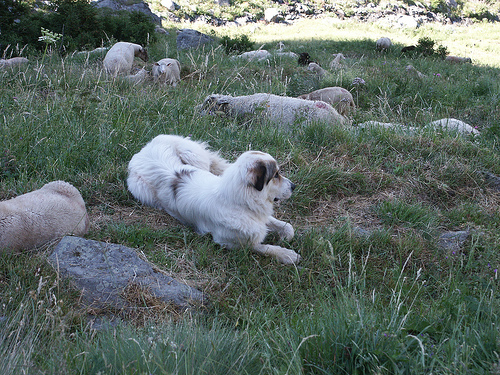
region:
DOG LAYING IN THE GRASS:
[125, 123, 317, 262]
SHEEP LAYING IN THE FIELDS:
[100, 41, 495, 156]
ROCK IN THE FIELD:
[42, 234, 214, 326]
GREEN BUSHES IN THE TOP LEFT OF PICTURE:
[2, 2, 183, 68]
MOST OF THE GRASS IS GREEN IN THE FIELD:
[3, 4, 488, 372]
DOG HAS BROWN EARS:
[235, 152, 297, 194]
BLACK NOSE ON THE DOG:
[282, 170, 299, 202]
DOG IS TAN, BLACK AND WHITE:
[123, 125, 322, 267]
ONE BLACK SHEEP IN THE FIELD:
[291, 46, 323, 76]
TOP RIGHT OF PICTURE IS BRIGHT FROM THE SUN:
[112, 0, 497, 78]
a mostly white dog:
[116, 112, 331, 315]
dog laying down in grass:
[107, 110, 322, 276]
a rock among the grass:
[44, 229, 224, 364]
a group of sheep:
[95, 20, 365, 134]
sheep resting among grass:
[90, 28, 368, 135]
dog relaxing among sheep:
[80, 33, 407, 258]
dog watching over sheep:
[67, 32, 434, 274]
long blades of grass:
[250, 258, 498, 355]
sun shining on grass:
[266, 8, 438, 70]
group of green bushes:
[4, 0, 139, 55]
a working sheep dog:
[104, 105, 336, 294]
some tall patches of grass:
[61, 278, 454, 371]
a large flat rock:
[25, 222, 228, 319]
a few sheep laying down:
[212, 2, 371, 154]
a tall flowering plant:
[37, 13, 74, 59]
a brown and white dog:
[127, 120, 320, 295]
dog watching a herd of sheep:
[9, 14, 480, 308]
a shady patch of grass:
[106, 12, 474, 313]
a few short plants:
[172, 0, 482, 40]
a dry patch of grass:
[317, 185, 378, 229]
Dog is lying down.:
[111, 116, 310, 267]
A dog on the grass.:
[107, 112, 358, 266]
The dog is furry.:
[123, 120, 323, 282]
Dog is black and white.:
[113, 117, 324, 295]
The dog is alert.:
[106, 122, 325, 277]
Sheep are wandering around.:
[88, 34, 494, 164]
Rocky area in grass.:
[6, 196, 498, 372]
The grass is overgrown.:
[0, 37, 498, 372]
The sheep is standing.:
[1, 37, 223, 169]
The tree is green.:
[2, 0, 165, 78]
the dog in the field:
[108, 119, 314, 267]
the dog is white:
[110, 124, 351, 275]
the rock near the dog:
[33, 239, 205, 316]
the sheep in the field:
[179, 81, 475, 156]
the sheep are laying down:
[91, 36, 379, 133]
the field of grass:
[48, 70, 448, 335]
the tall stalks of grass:
[18, 52, 158, 133]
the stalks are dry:
[331, 255, 433, 328]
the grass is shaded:
[51, 55, 461, 350]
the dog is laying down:
[118, 110, 320, 284]